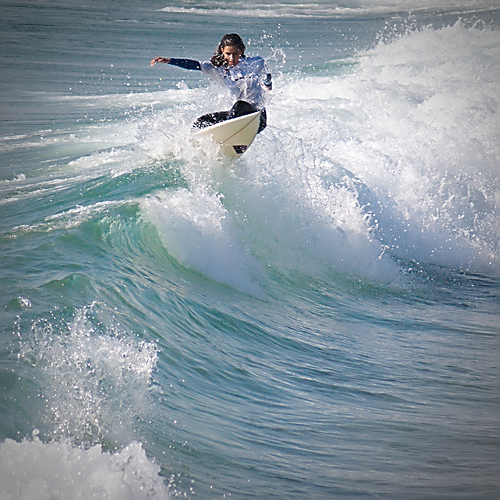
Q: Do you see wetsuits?
A: Yes, there is a wetsuit.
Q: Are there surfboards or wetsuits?
A: Yes, there is a wetsuit.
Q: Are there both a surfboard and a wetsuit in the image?
A: Yes, there are both a wetsuit and a surfboard.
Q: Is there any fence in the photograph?
A: No, there are no fences.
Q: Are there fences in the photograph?
A: No, there are no fences.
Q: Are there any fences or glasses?
A: No, there are no fences or glasses.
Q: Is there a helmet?
A: No, there are no helmets.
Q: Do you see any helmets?
A: No, there are no helmets.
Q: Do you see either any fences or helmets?
A: No, there are no helmets or fences.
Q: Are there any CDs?
A: No, there are no cds.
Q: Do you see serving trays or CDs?
A: No, there are no CDs or serving trays.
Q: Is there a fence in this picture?
A: No, there are no fences.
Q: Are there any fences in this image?
A: No, there are no fences.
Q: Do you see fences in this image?
A: No, there are no fences.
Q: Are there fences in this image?
A: No, there are no fences.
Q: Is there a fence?
A: No, there are no fences.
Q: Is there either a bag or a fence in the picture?
A: No, there are no fences or bags.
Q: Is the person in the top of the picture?
A: Yes, the person is in the top of the image.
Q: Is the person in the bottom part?
A: No, the person is in the top of the image.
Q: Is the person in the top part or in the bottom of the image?
A: The person is in the top of the image.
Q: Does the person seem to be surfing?
A: Yes, the person is surfing.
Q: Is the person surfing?
A: Yes, the person is surfing.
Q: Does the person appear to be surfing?
A: Yes, the person is surfing.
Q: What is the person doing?
A: The person is surfing.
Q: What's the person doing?
A: The person is surfing.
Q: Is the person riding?
A: No, the person is surfing.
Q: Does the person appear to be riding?
A: No, the person is surfing.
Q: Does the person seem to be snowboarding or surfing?
A: The person is surfing.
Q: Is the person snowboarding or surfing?
A: The person is surfing.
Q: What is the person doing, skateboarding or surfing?
A: The person is surfing.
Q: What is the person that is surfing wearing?
A: The person is wearing a wetsuit.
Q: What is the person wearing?
A: The person is wearing a wetsuit.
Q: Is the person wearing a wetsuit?
A: Yes, the person is wearing a wetsuit.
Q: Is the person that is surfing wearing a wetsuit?
A: Yes, the person is wearing a wetsuit.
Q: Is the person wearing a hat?
A: No, the person is wearing a wetsuit.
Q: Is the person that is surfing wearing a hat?
A: No, the person is wearing a wetsuit.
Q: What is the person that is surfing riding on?
A: The person is riding on the surfboard.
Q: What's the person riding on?
A: The person is riding on the surfboard.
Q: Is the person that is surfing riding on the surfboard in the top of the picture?
A: Yes, the person is riding on the surf board.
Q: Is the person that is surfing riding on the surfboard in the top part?
A: Yes, the person is riding on the surf board.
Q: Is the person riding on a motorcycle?
A: No, the person is riding on the surf board.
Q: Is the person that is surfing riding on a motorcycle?
A: No, the person is riding on the surf board.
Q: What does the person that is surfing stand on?
A: The person stands on the surfboard.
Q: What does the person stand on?
A: The person stands on the surfboard.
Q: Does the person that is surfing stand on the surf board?
A: Yes, the person stands on the surf board.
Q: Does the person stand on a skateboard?
A: No, the person stands on the surf board.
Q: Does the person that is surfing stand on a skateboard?
A: No, the person stands on the surf board.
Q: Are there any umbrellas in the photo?
A: No, there are no umbrellas.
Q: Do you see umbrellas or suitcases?
A: No, there are no umbrellas or suitcases.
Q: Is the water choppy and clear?
A: Yes, the water is choppy and clear.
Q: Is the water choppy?
A: Yes, the water is choppy.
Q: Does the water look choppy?
A: Yes, the water is choppy.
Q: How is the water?
A: The water is choppy.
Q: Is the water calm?
A: No, the water is choppy.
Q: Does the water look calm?
A: No, the water is choppy.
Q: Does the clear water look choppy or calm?
A: The water is choppy.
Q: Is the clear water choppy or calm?
A: The water is choppy.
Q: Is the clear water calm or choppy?
A: The water is choppy.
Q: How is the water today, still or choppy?
A: The water is choppy.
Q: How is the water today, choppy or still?
A: The water is choppy.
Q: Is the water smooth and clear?
A: No, the water is clear but choppy.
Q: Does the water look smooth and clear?
A: No, the water is clear but choppy.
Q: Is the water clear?
A: Yes, the water is clear.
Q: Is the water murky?
A: No, the water is clear.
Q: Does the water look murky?
A: No, the water is clear.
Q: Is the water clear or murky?
A: The water is clear.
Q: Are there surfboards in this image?
A: Yes, there is a surfboard.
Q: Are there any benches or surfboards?
A: Yes, there is a surfboard.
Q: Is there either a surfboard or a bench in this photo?
A: Yes, there is a surfboard.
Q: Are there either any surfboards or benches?
A: Yes, there is a surfboard.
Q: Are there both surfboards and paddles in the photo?
A: No, there is a surfboard but no paddles.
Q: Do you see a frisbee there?
A: No, there are no frisbees.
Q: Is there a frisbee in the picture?
A: No, there are no frisbees.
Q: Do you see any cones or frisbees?
A: No, there are no frisbees or cones.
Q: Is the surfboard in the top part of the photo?
A: Yes, the surfboard is in the top of the image.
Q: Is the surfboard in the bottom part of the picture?
A: No, the surfboard is in the top of the image.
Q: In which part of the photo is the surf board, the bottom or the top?
A: The surf board is in the top of the image.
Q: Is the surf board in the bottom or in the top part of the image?
A: The surf board is in the top of the image.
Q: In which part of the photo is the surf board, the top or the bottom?
A: The surf board is in the top of the image.